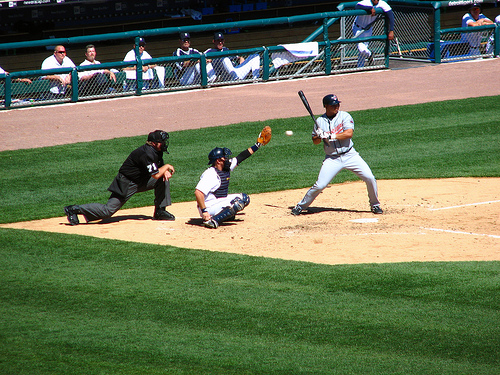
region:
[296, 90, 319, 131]
a black bat in a man's hand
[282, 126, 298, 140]
a baseball in the air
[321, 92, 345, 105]
a black helmet on a man's head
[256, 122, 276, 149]
a brown catcher's mitt held out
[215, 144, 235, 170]
a black catcher's mask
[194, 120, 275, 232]
a catcher behind a batter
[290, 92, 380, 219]
a batter in a light grey uniform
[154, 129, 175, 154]
a black mask on an umpire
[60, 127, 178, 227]
an umpire behind a catcher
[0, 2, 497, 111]
the dugout at a baseball field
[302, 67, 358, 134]
the head of a man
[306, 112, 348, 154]
the hand of a man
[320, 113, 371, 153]
the arm of a man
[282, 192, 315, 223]
the foot of a man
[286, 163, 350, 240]
the leg of a man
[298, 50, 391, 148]
a man holding a bat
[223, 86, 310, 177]
a man wearing a baseball glove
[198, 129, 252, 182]
a man wearing a face mask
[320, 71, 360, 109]
a man wearing a hat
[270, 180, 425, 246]
a man wearing shoes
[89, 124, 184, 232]
this is a person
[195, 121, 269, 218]
this is a person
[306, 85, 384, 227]
this is a person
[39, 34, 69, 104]
this is a person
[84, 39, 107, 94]
this is a person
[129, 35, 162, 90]
this is a person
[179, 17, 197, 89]
this is a person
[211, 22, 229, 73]
this is a person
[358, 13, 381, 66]
this is a person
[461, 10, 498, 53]
this is a person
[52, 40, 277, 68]
people watching the players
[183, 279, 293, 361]
field is green in color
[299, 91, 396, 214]
man is dressed in grey outfit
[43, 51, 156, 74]
the shirts are white in color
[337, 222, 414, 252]
the floor is browm n in color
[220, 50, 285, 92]
the p[ants are white in color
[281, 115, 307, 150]
the ball is in th air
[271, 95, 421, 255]
man is hitting a ball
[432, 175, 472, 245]
the floor has white stripes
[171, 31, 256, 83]
the fence is dull blue in color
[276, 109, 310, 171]
ball in the air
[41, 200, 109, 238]
knee touching the ground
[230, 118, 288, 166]
mitt catching the ball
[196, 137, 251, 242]
catcher sitting on the ground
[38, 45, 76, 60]
man with glasses on face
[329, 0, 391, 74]
man leaning over fence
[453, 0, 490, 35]
person with arms crossed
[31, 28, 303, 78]
men watching the game